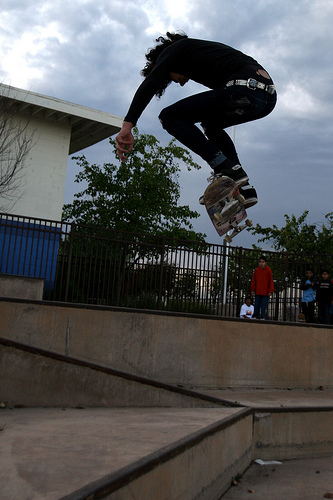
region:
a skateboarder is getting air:
[85, 23, 292, 293]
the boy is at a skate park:
[7, 7, 332, 495]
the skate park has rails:
[7, 336, 330, 494]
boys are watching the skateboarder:
[228, 247, 332, 335]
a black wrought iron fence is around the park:
[2, 205, 332, 332]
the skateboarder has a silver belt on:
[221, 75, 280, 98]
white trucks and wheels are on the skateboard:
[210, 191, 255, 250]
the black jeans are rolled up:
[158, 85, 278, 165]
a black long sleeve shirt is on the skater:
[121, 38, 278, 125]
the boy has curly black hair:
[137, 24, 209, 100]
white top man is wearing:
[239, 303, 254, 317]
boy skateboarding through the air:
[115, 30, 277, 244]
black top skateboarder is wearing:
[122, 38, 274, 123]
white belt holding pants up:
[224, 78, 277, 93]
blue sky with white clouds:
[0, 0, 332, 252]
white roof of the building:
[0, 81, 124, 151]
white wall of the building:
[0, 110, 71, 228]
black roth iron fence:
[0, 210, 331, 321]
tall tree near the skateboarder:
[32, 116, 212, 321]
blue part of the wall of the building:
[0, 219, 63, 311]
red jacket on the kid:
[248, 265, 276, 295]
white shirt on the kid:
[239, 303, 254, 317]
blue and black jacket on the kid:
[297, 276, 316, 302]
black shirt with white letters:
[313, 279, 332, 299]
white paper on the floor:
[254, 456, 283, 466]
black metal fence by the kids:
[0, 209, 331, 326]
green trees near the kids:
[210, 208, 331, 321]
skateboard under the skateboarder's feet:
[203, 175, 254, 243]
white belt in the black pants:
[225, 77, 278, 97]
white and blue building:
[0, 81, 123, 295]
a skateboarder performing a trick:
[114, 31, 277, 247]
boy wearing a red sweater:
[249, 265, 274, 296]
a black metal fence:
[0, 212, 332, 327]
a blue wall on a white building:
[0, 217, 60, 290]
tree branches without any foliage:
[1, 77, 38, 220]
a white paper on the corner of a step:
[255, 457, 282, 467]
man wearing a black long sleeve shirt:
[123, 37, 272, 123]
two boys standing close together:
[299, 269, 331, 323]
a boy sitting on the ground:
[238, 297, 255, 319]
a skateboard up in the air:
[203, 174, 252, 244]